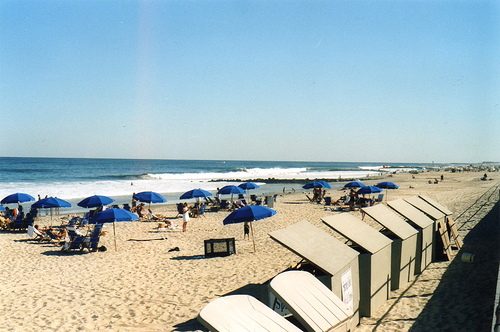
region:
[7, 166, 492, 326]
people on a sandy beach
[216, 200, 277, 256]
blue umbrella in the sand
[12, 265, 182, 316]
tan sand on the beach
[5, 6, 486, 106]
blue sky in the distance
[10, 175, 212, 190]
white waves crashing into shore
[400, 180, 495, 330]
shadow of boardwalk cast onto the sand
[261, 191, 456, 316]
wooden bins with beach supplies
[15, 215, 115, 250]
people relaxing on the beach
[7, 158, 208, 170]
blue waters of the ocean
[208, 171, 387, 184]
rocky area in the water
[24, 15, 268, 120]
Pretty blue skies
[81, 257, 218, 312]
Footprints in the sand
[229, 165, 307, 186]
White waves hitting the shore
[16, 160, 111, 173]
Blue water extending to the horizon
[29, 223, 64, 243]
A person reclining in a chair at the beach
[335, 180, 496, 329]
A shadow from a railing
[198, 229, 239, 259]
A black playpen covered by an umbrella's shadow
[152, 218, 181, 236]
A child building a sandcastle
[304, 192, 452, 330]
Bins lined up in a row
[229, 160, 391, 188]
A circular retaining wall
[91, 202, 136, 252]
an umbrella in the beach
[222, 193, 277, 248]
an umbrella in the beach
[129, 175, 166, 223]
an umbrella in the beach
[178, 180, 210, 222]
an umbrella in the beach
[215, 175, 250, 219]
an umbrella in the beach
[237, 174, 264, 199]
an umbrella in the beach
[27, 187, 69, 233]
an umbrella in the beach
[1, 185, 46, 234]
an umbrella in the beach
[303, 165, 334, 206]
an umbrella in the beach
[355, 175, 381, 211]
an umbrella in the beach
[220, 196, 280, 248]
a blue beach umbrella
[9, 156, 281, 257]
a group of people under beach umbrellas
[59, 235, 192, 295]
a sandy beach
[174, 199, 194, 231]
a lady in a white beach coverup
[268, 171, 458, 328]
a row of dumpsters on the beach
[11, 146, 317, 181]
a blue ocean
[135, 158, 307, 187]
waves breaking on the shore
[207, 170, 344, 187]
a rock jetty in the ocean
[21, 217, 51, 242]
a person laying on a beach chair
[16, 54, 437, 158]
a clear blue sky over the ocean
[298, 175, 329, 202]
an umbrella in the beach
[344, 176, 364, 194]
an umbrella in the beach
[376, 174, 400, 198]
an umbrella in the beach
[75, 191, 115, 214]
an umbrella in the beach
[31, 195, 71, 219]
an umbrella in the beach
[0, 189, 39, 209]
an umbrella in the beach